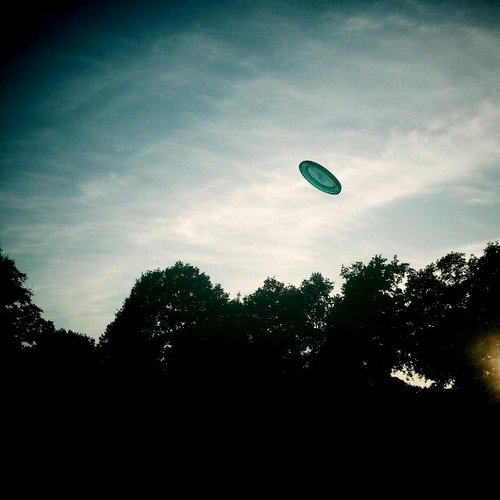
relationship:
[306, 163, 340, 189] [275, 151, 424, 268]
circle on frisbee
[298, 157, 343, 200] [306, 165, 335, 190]
frisbee has circle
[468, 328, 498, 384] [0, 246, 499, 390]
light shining on trees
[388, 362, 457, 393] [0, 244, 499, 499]
light shining shining through trees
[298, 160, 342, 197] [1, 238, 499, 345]
frisbee flying above tree line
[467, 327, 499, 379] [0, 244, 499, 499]
glimmer shining through trees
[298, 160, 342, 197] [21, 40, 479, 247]
frisbee in air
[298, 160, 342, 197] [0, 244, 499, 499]
frisbee under trees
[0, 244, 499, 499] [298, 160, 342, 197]
trees under frisbee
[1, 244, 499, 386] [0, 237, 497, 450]
outline of trees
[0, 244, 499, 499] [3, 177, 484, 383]
trees in background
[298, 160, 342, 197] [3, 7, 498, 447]
frisbee in air